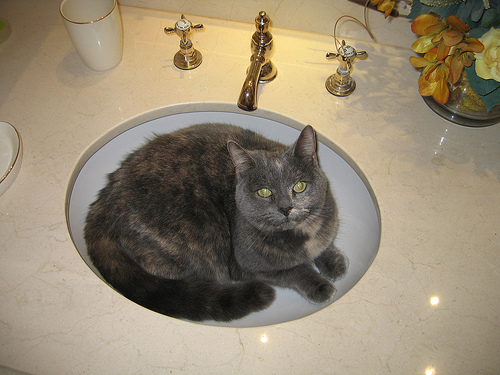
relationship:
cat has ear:
[85, 120, 351, 322] [290, 124, 319, 163]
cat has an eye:
[85, 120, 351, 322] [255, 187, 272, 198]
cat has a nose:
[85, 120, 351, 322] [277, 204, 294, 217]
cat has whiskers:
[85, 120, 351, 322] [296, 208, 342, 244]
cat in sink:
[85, 120, 351, 322] [63, 99, 384, 331]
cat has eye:
[85, 120, 351, 322] [255, 187, 272, 198]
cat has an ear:
[85, 120, 351, 322] [290, 124, 319, 163]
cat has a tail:
[85, 120, 351, 322] [84, 225, 273, 323]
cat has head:
[85, 120, 351, 322] [226, 125, 329, 230]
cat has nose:
[85, 120, 351, 322] [277, 204, 294, 217]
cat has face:
[85, 120, 351, 322] [236, 171, 327, 228]